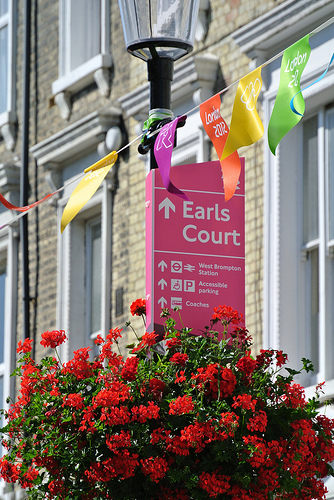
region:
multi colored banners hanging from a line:
[63, 122, 253, 217]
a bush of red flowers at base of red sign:
[15, 304, 321, 489]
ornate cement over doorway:
[27, 121, 127, 188]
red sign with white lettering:
[142, 155, 263, 338]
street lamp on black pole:
[111, 2, 208, 122]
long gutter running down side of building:
[14, 28, 46, 280]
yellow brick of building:
[120, 170, 139, 239]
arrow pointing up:
[154, 196, 182, 224]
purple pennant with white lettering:
[155, 124, 197, 198]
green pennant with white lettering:
[270, 37, 314, 155]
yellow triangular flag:
[13, 150, 112, 228]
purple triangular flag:
[150, 130, 191, 222]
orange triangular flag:
[199, 102, 232, 204]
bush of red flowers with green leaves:
[5, 329, 271, 490]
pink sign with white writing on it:
[157, 174, 257, 336]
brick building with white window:
[23, 84, 134, 341]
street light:
[120, 1, 209, 167]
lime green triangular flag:
[285, 52, 322, 153]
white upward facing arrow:
[161, 192, 189, 228]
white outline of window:
[262, 146, 321, 396]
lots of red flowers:
[0, 297, 332, 497]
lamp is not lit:
[117, 0, 200, 172]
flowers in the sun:
[1, 294, 331, 496]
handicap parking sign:
[154, 274, 231, 294]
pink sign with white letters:
[138, 153, 255, 350]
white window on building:
[51, 177, 115, 370]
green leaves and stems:
[0, 304, 330, 495]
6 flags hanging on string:
[0, 22, 328, 237]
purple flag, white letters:
[148, 114, 187, 200]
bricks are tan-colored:
[110, 138, 146, 343]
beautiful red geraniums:
[15, 270, 317, 493]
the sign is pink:
[151, 157, 287, 358]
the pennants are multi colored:
[43, 12, 321, 244]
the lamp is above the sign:
[110, 5, 218, 138]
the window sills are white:
[33, 46, 108, 117]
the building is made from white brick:
[118, 208, 137, 271]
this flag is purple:
[139, 99, 195, 234]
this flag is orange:
[200, 82, 232, 202]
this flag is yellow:
[48, 143, 116, 246]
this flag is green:
[266, 27, 332, 170]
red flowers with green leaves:
[8, 307, 131, 492]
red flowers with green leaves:
[115, 339, 244, 495]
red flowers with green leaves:
[223, 337, 323, 493]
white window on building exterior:
[266, 146, 332, 348]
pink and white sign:
[151, 163, 254, 301]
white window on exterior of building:
[37, 230, 124, 324]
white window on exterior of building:
[35, 12, 117, 105]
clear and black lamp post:
[107, 10, 219, 100]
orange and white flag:
[4, 187, 59, 227]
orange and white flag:
[188, 93, 250, 208]